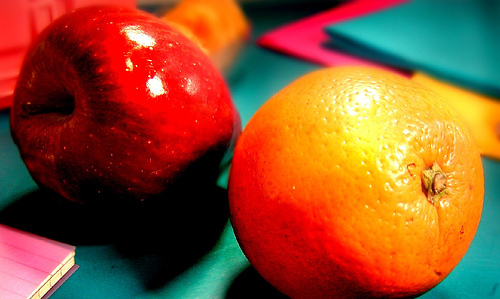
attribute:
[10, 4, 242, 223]
apple — red 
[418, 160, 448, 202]
stem — broken 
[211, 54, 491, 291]
orange — shiny 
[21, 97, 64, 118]
stem — short 